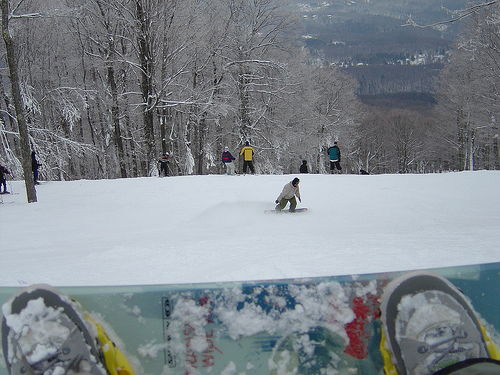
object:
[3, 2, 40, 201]
tree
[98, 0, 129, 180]
tree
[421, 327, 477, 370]
laces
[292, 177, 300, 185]
black hat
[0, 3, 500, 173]
snow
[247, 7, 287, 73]
tree branches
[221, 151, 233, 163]
jacket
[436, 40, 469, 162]
tree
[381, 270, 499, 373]
sneaker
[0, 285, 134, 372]
sneaker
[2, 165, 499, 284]
snow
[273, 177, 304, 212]
person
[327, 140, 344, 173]
person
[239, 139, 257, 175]
person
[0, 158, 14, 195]
person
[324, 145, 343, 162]
green jacket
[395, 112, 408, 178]
tree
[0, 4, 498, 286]
field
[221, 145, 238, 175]
person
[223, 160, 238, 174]
pants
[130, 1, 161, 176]
tree trunk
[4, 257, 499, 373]
snow board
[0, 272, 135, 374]
shoes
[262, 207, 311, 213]
board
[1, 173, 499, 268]
ground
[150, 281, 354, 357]
snow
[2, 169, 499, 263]
ski surface